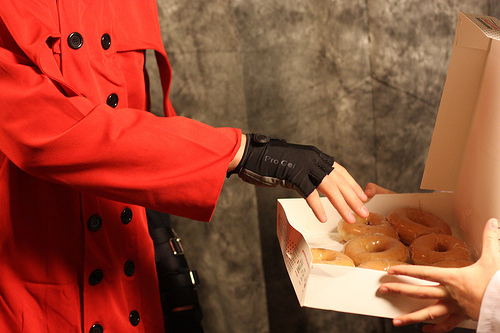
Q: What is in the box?
A: Donuts.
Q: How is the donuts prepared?
A: They are glazed.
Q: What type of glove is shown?
A: Fingerless.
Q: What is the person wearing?
A: A red coat.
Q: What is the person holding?
A: Box of donuts.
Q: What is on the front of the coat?
A: Black buttons.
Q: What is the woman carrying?
A: A purse.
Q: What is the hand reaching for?
A: Donuts.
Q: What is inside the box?
A: Donuts.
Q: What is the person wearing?
A: A trench coat.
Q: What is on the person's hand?
A: A fingerless glove.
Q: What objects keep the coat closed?
A: Buttons.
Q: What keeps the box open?
A: Hands of a person.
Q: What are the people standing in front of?
A: A wall.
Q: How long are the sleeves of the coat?
A: Long.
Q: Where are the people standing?
A: Near a building.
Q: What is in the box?
A: Glazed donuts.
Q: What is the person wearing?
A: A red coat.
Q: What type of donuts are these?
A: They are glazed donuts.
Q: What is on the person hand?
A: A black glove.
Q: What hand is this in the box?
A: The right hand.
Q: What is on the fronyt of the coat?
A: Black buttons.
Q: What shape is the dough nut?
A: Round cicrles.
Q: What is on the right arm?
A: Red coat sleeve.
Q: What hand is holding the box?
A: The left hand.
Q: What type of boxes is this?
A: A white box with a lid.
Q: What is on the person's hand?
A: Fingerless gloves.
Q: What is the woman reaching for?
A: A doughnut.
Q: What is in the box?
A: Doughnuts.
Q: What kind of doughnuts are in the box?
A: Glazed.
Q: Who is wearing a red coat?
A: The woman reaching for the doughnut.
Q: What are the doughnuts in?
A: A white cardboard box.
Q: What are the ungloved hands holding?
A: A box of doughnuts.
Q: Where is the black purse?
A: At the woman's side.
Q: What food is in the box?
A: Doughnuts.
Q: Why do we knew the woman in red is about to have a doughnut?
A: She is reaching into the box.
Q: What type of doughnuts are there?
A: Glazed.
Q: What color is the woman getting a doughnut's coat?
A: Red.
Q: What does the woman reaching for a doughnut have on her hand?
A: A fingerless glove.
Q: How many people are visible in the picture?
A: Two.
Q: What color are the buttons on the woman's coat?
A: Black.